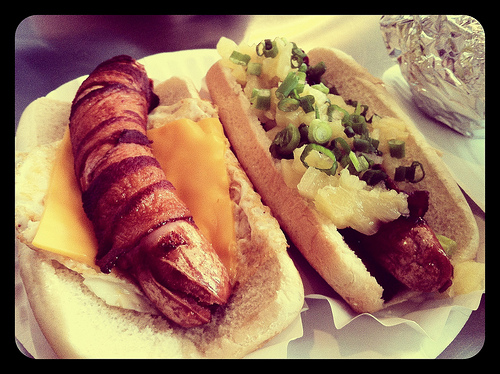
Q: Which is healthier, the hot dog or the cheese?
A: The cheese is healthier than the hot dog.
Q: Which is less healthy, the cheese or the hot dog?
A: The hot dog is less healthy than the cheese.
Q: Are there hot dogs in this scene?
A: Yes, there is a hot dog.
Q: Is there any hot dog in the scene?
A: Yes, there is a hot dog.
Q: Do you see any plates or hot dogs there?
A: Yes, there is a hot dog.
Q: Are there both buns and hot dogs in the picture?
A: Yes, there are both a hot dog and a bun.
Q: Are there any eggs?
A: No, there are no eggs.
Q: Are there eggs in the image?
A: No, there are no eggs.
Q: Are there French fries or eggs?
A: No, there are no eggs or French fries.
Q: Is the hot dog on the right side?
A: Yes, the hot dog is on the right of the image.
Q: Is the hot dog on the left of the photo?
A: No, the hot dog is on the right of the image.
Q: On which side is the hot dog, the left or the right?
A: The hot dog is on the right of the image.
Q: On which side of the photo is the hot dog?
A: The hot dog is on the right of the image.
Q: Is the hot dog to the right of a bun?
A: Yes, the hot dog is to the right of a bun.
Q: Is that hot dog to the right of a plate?
A: No, the hot dog is to the right of a bun.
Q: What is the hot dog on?
A: The hot dog is on the paper.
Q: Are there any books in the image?
A: No, there are no books.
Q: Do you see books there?
A: No, there are no books.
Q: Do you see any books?
A: No, there are no books.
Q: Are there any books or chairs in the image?
A: No, there are no books or chairs.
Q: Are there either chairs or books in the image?
A: No, there are no books or chairs.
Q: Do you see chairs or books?
A: No, there are no books or chairs.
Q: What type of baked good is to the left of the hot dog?
A: The food is a bun.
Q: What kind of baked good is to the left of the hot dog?
A: The food is a bun.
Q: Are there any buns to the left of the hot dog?
A: Yes, there is a bun to the left of the hot dog.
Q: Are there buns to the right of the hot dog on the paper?
A: No, the bun is to the left of the hot dog.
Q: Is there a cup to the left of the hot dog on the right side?
A: No, there is a bun to the left of the hot dog.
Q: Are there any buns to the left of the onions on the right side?
A: Yes, there is a bun to the left of the onions.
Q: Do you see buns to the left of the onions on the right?
A: Yes, there is a bun to the left of the onions.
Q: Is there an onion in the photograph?
A: Yes, there are onions.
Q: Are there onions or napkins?
A: Yes, there are onions.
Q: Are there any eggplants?
A: No, there are no eggplants.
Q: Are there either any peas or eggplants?
A: No, there are no eggplants or peas.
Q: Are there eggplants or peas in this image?
A: No, there are no eggplants or peas.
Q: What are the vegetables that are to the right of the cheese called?
A: The vegetables are onions.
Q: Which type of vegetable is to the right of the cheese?
A: The vegetables are onions.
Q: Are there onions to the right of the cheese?
A: Yes, there are onions to the right of the cheese.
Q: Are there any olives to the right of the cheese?
A: No, there are onions to the right of the cheese.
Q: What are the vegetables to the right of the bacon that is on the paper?
A: The vegetables are onions.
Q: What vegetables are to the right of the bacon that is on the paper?
A: The vegetables are onions.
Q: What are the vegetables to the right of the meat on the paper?
A: The vegetables are onions.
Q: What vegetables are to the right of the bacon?
A: The vegetables are onions.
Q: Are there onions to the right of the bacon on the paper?
A: Yes, there are onions to the right of the bacon.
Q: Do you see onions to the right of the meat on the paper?
A: Yes, there are onions to the right of the bacon.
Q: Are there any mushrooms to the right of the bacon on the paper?
A: No, there are onions to the right of the bacon.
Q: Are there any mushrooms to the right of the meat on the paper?
A: No, there are onions to the right of the bacon.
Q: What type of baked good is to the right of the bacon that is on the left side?
A: The food is a bun.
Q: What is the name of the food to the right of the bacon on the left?
A: The food is a bun.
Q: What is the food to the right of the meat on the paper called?
A: The food is a bun.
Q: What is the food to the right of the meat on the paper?
A: The food is a bun.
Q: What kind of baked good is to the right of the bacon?
A: The food is a bun.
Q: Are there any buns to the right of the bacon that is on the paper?
A: Yes, there is a bun to the right of the bacon.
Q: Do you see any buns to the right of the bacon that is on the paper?
A: Yes, there is a bun to the right of the bacon.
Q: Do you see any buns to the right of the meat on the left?
A: Yes, there is a bun to the right of the bacon.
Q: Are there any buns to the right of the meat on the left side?
A: Yes, there is a bun to the right of the bacon.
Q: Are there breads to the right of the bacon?
A: No, there is a bun to the right of the bacon.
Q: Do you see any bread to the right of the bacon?
A: No, there is a bun to the right of the bacon.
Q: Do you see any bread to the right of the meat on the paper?
A: No, there is a bun to the right of the bacon.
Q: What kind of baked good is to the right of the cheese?
A: The food is a bun.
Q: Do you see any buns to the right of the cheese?
A: Yes, there is a bun to the right of the cheese.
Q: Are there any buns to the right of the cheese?
A: Yes, there is a bun to the right of the cheese.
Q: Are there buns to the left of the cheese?
A: No, the bun is to the right of the cheese.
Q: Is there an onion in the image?
A: Yes, there is an onion.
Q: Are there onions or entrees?
A: Yes, there is an onion.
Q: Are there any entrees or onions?
A: Yes, there is an onion.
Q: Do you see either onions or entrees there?
A: Yes, there is an onion.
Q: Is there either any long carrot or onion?
A: Yes, there is a long onion.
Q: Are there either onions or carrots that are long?
A: Yes, the onion is long.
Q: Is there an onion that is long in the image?
A: Yes, there is a long onion.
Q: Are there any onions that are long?
A: Yes, there is an onion that is long.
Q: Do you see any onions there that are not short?
A: Yes, there is a long onion.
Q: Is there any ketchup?
A: Yes, there is ketchup.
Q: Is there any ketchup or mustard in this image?
A: Yes, there is ketchup.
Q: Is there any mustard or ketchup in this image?
A: Yes, there is ketchup.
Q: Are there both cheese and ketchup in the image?
A: Yes, there are both ketchup and cheese.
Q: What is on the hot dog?
A: The ketchup is on the hot dog.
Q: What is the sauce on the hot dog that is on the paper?
A: The sauce is ketchup.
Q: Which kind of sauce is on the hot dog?
A: The sauce is ketchup.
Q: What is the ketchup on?
A: The ketchup is on the hot dog.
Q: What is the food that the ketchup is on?
A: The food is a hot dog.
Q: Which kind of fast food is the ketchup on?
A: The ketchup is on the hot dog.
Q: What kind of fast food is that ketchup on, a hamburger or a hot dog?
A: The ketchup is on a hot dog.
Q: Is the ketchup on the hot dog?
A: Yes, the ketchup is on the hot dog.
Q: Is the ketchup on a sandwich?
A: No, the ketchup is on the hot dog.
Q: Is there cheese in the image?
A: Yes, there is cheese.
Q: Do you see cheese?
A: Yes, there is cheese.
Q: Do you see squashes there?
A: No, there are no squashes.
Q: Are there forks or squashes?
A: No, there are no squashes or forks.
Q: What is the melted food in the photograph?
A: The food is cheese.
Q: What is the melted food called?
A: The food is cheese.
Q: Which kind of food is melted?
A: The food is cheese.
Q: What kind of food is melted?
A: The food is cheese.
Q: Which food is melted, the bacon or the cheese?
A: The cheese is melted.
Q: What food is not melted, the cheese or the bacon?
A: The bacon is not melted.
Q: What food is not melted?
A: The food is bacon.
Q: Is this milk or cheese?
A: This is cheese.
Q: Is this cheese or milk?
A: This is cheese.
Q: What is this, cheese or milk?
A: This is cheese.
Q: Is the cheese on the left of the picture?
A: Yes, the cheese is on the left of the image.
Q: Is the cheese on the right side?
A: No, the cheese is on the left of the image.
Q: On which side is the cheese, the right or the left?
A: The cheese is on the left of the image.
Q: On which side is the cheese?
A: The cheese is on the left of the image.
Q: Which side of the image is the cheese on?
A: The cheese is on the left of the image.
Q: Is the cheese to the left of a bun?
A: Yes, the cheese is to the left of a bun.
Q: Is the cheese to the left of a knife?
A: No, the cheese is to the left of a bun.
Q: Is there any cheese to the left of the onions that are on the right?
A: Yes, there is cheese to the left of the onions.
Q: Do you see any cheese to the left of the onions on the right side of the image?
A: Yes, there is cheese to the left of the onions.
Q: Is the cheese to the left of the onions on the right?
A: Yes, the cheese is to the left of the onions.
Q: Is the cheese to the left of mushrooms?
A: No, the cheese is to the left of the onions.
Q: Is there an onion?
A: Yes, there is an onion.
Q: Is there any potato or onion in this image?
A: Yes, there is an onion.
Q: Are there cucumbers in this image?
A: No, there are no cucumbers.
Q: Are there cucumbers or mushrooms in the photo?
A: No, there are no cucumbers or mushrooms.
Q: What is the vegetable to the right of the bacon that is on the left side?
A: The vegetable is an onion.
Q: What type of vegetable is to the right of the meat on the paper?
A: The vegetable is an onion.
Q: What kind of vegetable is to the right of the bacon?
A: The vegetable is an onion.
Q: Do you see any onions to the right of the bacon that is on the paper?
A: Yes, there is an onion to the right of the bacon.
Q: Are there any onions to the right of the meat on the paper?
A: Yes, there is an onion to the right of the bacon.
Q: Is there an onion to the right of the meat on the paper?
A: Yes, there is an onion to the right of the bacon.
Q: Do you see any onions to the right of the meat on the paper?
A: Yes, there is an onion to the right of the bacon.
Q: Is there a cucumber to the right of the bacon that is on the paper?
A: No, there is an onion to the right of the bacon.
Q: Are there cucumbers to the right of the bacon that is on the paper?
A: No, there is an onion to the right of the bacon.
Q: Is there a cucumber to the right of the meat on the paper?
A: No, there is an onion to the right of the bacon.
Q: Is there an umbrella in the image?
A: No, there are no umbrellas.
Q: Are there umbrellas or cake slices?
A: No, there are no umbrellas or cake slices.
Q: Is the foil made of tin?
A: Yes, the foil is made of tin.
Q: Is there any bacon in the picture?
A: Yes, there is bacon.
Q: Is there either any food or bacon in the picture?
A: Yes, there is bacon.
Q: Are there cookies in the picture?
A: No, there are no cookies.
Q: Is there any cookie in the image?
A: No, there are no cookies.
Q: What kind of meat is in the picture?
A: The meat is bacon.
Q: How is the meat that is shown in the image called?
A: The meat is bacon.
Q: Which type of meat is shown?
A: The meat is bacon.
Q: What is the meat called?
A: The meat is bacon.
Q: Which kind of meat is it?
A: The meat is bacon.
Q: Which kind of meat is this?
A: This is bacon.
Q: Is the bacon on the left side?
A: Yes, the bacon is on the left of the image.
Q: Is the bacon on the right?
A: No, the bacon is on the left of the image.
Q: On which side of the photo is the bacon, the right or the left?
A: The bacon is on the left of the image.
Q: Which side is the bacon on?
A: The bacon is on the left of the image.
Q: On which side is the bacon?
A: The bacon is on the left of the image.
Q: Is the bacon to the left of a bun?
A: Yes, the bacon is to the left of a bun.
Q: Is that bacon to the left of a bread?
A: No, the bacon is to the left of a bun.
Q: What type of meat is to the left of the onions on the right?
A: The meat is bacon.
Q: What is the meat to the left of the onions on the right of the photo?
A: The meat is bacon.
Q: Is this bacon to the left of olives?
A: No, the bacon is to the left of the onions.